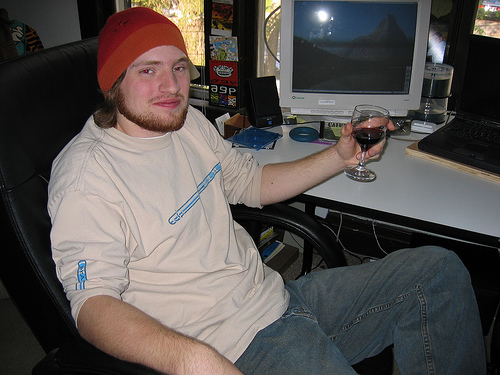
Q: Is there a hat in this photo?
A: Yes, there is a hat.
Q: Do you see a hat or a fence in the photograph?
A: Yes, there is a hat.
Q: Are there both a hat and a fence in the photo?
A: No, there is a hat but no fences.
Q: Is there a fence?
A: No, there are no fences.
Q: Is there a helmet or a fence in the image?
A: No, there are no fences or helmets.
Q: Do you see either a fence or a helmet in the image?
A: No, there are no fences or helmets.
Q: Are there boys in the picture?
A: No, there are no boys.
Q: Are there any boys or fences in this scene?
A: No, there are no boys or fences.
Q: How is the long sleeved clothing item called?
A: The clothing item is a shirt.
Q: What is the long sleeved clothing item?
A: The clothing item is a shirt.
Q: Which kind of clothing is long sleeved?
A: The clothing is a shirt.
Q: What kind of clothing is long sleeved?
A: The clothing is a shirt.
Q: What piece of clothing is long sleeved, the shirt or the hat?
A: The shirt is long sleeved.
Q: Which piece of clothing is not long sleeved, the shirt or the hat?
A: The hat is not long sleeved.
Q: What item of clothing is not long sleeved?
A: The clothing item is a hat.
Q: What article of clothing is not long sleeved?
A: The clothing item is a hat.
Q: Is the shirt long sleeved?
A: Yes, the shirt is long sleeved.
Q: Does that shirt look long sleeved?
A: Yes, the shirt is long sleeved.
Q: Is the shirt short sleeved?
A: No, the shirt is long sleeved.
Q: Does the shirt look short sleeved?
A: No, the shirt is long sleeved.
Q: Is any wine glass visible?
A: Yes, there is a wine glass.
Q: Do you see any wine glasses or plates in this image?
A: Yes, there is a wine glass.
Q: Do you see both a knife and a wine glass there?
A: No, there is a wine glass but no knives.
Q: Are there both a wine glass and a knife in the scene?
A: No, there is a wine glass but no knives.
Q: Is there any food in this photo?
A: No, there is no food.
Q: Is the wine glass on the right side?
A: Yes, the wine glass is on the right of the image.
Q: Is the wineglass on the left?
A: No, the wineglass is on the right of the image.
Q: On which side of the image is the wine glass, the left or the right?
A: The wine glass is on the right of the image.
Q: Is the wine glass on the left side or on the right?
A: The wine glass is on the right of the image.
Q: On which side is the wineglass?
A: The wineglass is on the right of the image.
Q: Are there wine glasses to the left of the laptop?
A: Yes, there is a wine glass to the left of the laptop.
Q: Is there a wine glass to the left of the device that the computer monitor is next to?
A: Yes, there is a wine glass to the left of the laptop.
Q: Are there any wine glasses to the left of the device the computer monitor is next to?
A: Yes, there is a wine glass to the left of the laptop.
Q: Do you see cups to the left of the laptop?
A: No, there is a wine glass to the left of the laptop.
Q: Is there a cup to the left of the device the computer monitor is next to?
A: No, there is a wine glass to the left of the laptop.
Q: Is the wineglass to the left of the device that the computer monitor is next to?
A: Yes, the wineglass is to the left of the laptop.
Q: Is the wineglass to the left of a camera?
A: No, the wineglass is to the left of the laptop.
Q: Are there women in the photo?
A: No, there are no women.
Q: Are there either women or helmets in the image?
A: No, there are no women or helmets.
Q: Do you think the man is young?
A: Yes, the man is young.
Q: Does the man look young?
A: Yes, the man is young.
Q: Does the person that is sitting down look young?
A: Yes, the man is young.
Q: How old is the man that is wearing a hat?
A: The man is young.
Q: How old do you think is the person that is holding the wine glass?
A: The man is young.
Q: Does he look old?
A: No, the man is young.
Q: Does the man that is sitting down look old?
A: No, the man is young.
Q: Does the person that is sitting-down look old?
A: No, the man is young.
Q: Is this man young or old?
A: The man is young.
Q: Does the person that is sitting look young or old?
A: The man is young.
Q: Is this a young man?
A: Yes, this is a young man.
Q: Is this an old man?
A: No, this is a young man.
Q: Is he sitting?
A: Yes, the man is sitting.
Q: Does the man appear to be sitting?
A: Yes, the man is sitting.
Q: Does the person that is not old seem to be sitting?
A: Yes, the man is sitting.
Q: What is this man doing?
A: The man is sitting.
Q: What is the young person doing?
A: The man is sitting.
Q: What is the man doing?
A: The man is sitting.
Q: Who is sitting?
A: The man is sitting.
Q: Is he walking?
A: No, the man is sitting.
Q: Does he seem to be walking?
A: No, the man is sitting.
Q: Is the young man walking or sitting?
A: The man is sitting.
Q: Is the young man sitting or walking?
A: The man is sitting.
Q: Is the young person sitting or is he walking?
A: The man is sitting.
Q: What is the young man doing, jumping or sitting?
A: The man is sitting.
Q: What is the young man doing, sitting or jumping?
A: The man is sitting.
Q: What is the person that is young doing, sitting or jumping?
A: The man is sitting.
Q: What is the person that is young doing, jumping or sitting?
A: The man is sitting.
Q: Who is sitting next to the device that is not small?
A: The man is sitting next to the computer monitor.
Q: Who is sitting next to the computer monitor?
A: The man is sitting next to the computer monitor.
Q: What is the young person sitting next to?
A: The man is sitting next to the computer monitor.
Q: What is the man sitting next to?
A: The man is sitting next to the computer monitor.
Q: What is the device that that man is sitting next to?
A: The device is a computer monitor.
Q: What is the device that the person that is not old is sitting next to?
A: The device is a computer monitor.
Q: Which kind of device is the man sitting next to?
A: The man is sitting next to the computer monitor.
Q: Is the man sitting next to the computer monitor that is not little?
A: Yes, the man is sitting next to the computer monitor.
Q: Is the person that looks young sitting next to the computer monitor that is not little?
A: Yes, the man is sitting next to the computer monitor.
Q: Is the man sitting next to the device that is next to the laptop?
A: Yes, the man is sitting next to the computer monitor.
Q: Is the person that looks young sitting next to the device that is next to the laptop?
A: Yes, the man is sitting next to the computer monitor.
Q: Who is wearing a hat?
A: The man is wearing a hat.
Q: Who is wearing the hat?
A: The man is wearing a hat.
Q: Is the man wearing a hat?
A: Yes, the man is wearing a hat.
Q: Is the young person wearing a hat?
A: Yes, the man is wearing a hat.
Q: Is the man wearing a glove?
A: No, the man is wearing a hat.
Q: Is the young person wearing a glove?
A: No, the man is wearing a hat.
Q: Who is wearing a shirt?
A: The man is wearing a shirt.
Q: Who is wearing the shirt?
A: The man is wearing a shirt.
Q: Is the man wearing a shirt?
A: Yes, the man is wearing a shirt.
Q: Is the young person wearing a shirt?
A: Yes, the man is wearing a shirt.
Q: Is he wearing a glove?
A: No, the man is wearing a shirt.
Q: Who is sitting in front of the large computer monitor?
A: The man is sitting in front of the computer monitor.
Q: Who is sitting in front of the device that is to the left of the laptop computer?
A: The man is sitting in front of the computer monitor.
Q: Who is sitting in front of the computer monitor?
A: The man is sitting in front of the computer monitor.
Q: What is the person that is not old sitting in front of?
A: The man is sitting in front of the computer monitor.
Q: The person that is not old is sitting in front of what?
A: The man is sitting in front of the computer monitor.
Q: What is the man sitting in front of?
A: The man is sitting in front of the computer monitor.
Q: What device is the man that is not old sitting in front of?
A: The man is sitting in front of the computer monitor.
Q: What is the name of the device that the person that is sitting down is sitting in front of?
A: The device is a computer monitor.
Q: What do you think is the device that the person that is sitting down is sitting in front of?
A: The device is a computer monitor.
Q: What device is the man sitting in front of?
A: The man is sitting in front of the computer monitor.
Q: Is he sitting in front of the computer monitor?
A: Yes, the man is sitting in front of the computer monitor.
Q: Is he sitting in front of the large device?
A: Yes, the man is sitting in front of the computer monitor.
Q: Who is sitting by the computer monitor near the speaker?
A: The man is sitting by the computer monitor.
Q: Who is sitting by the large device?
A: The man is sitting by the computer monitor.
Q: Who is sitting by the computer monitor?
A: The man is sitting by the computer monitor.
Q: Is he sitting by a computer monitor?
A: Yes, the man is sitting by a computer monitor.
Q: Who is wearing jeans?
A: The man is wearing jeans.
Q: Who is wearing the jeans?
A: The man is wearing jeans.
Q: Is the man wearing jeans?
A: Yes, the man is wearing jeans.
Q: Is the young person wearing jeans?
A: Yes, the man is wearing jeans.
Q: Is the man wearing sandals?
A: No, the man is wearing jeans.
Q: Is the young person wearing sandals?
A: No, the man is wearing jeans.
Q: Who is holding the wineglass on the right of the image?
A: The man is holding the wine glass.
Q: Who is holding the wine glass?
A: The man is holding the wine glass.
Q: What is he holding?
A: The man is holding the wine glass.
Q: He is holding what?
A: The man is holding the wine glass.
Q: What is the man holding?
A: The man is holding the wine glass.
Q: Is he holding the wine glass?
A: Yes, the man is holding the wine glass.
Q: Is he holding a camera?
A: No, the man is holding the wine glass.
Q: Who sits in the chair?
A: The man sits in the chair.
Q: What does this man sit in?
A: The man sits in the chair.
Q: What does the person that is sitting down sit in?
A: The man sits in the chair.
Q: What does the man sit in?
A: The man sits in the chair.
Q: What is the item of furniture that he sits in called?
A: The piece of furniture is a chair.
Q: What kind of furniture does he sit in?
A: The man sits in the chair.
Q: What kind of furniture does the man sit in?
A: The man sits in the chair.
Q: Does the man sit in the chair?
A: Yes, the man sits in the chair.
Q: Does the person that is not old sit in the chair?
A: Yes, the man sits in the chair.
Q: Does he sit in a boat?
A: No, the man sits in the chair.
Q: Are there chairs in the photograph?
A: Yes, there is a chair.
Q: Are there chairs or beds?
A: Yes, there is a chair.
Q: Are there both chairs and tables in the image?
A: Yes, there are both a chair and a table.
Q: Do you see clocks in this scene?
A: No, there are no clocks.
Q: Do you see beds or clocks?
A: No, there are no clocks or beds.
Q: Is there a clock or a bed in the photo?
A: No, there are no clocks or beds.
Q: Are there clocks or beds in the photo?
A: No, there are no clocks or beds.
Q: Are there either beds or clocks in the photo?
A: No, there are no clocks or beds.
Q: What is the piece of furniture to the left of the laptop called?
A: The piece of furniture is a chair.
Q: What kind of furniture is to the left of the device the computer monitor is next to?
A: The piece of furniture is a chair.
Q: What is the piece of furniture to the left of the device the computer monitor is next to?
A: The piece of furniture is a chair.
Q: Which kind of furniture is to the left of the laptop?
A: The piece of furniture is a chair.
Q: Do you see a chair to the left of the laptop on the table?
A: Yes, there is a chair to the left of the laptop computer.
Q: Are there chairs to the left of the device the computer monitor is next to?
A: Yes, there is a chair to the left of the laptop computer.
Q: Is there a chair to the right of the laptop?
A: No, the chair is to the left of the laptop.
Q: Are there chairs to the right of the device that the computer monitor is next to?
A: No, the chair is to the left of the laptop.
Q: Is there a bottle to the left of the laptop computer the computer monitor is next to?
A: No, there is a chair to the left of the laptop.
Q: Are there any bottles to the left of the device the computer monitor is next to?
A: No, there is a chair to the left of the laptop.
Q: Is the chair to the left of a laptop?
A: Yes, the chair is to the left of a laptop.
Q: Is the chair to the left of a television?
A: No, the chair is to the left of a laptop.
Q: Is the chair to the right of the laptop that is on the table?
A: No, the chair is to the left of the laptop computer.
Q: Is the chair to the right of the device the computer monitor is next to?
A: No, the chair is to the left of the laptop computer.